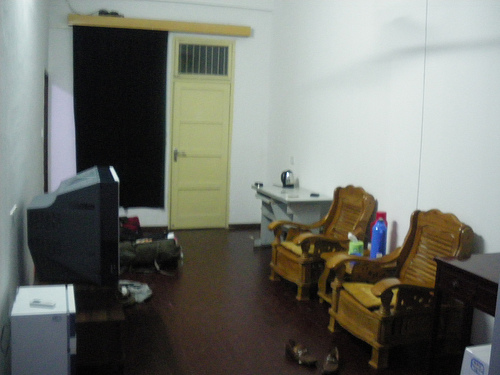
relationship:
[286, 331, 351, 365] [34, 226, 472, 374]
shoes on floor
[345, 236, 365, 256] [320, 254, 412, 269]
tissues on table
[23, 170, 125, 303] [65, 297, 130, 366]
tv on stand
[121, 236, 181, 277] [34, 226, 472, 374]
duffle bag on floor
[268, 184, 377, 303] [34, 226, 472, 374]
chair on floor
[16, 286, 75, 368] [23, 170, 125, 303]
refrigerator next to tv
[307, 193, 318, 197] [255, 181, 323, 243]
phone on table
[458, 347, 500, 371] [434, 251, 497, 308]
white box under table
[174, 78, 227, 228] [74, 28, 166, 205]
door next to curtains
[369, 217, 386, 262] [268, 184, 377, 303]
bottle between chair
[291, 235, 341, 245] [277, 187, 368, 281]
arm on chair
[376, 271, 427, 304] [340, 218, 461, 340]
arm of chair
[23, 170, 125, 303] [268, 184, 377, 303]
tv in front of chair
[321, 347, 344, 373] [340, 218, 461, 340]
shoe in front of chair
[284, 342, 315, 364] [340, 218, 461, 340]
shoe in front of chair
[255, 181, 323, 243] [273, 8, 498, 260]
desk in front of wall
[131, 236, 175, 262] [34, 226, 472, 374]
duffle bag on floor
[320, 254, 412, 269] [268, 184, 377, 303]
table between chair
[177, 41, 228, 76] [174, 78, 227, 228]
vent above door